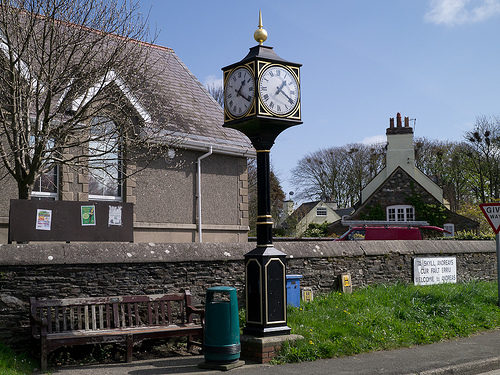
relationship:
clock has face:
[222, 45, 305, 149] [258, 62, 301, 116]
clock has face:
[222, 45, 305, 149] [222, 65, 257, 119]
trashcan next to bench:
[201, 286, 241, 362] [27, 288, 206, 373]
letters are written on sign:
[421, 266, 452, 274] [412, 256, 457, 286]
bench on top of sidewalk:
[27, 288, 206, 373] [35, 324, 498, 375]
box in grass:
[284, 273, 303, 310] [238, 277, 498, 364]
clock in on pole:
[222, 45, 305, 149] [255, 148, 276, 247]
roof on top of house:
[1, 4, 258, 157] [1, 2, 257, 244]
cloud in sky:
[422, 1, 500, 27] [1, 1, 500, 214]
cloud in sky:
[200, 75, 227, 95] [1, 1, 500, 214]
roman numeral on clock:
[261, 85, 268, 90] [222, 45, 305, 149]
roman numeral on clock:
[263, 93, 270, 101] [222, 45, 305, 149]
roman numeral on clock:
[270, 100, 276, 108] [222, 45, 305, 149]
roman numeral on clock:
[276, 104, 281, 112] [222, 45, 305, 149]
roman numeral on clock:
[284, 104, 289, 112] [222, 45, 305, 149]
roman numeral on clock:
[288, 99, 295, 105] [222, 45, 305, 149]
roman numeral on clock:
[290, 90, 297, 95] [222, 45, 305, 149]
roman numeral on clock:
[287, 80, 293, 85] [222, 45, 305, 149]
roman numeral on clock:
[283, 73, 288, 80] [222, 45, 305, 149]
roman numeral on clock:
[275, 69, 281, 77] [222, 45, 305, 149]